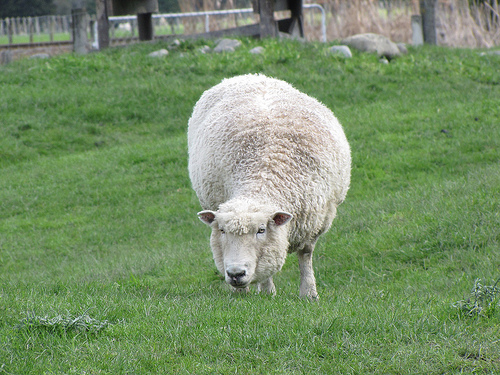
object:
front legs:
[298, 235, 321, 300]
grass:
[348, 293, 414, 335]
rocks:
[327, 30, 410, 63]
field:
[20, 63, 138, 318]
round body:
[184, 72, 354, 251]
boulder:
[336, 32, 401, 59]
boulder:
[323, 44, 353, 60]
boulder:
[210, 37, 246, 56]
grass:
[0, 71, 121, 116]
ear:
[269, 210, 295, 226]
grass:
[355, 147, 461, 171]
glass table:
[366, 205, 466, 345]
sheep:
[187, 70, 352, 299]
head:
[196, 198, 294, 289]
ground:
[431, 89, 449, 120]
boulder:
[247, 45, 265, 54]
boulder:
[325, 43, 353, 56]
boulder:
[340, 31, 402, 56]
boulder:
[213, 37, 240, 53]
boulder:
[194, 43, 211, 55]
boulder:
[146, 47, 171, 57]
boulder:
[170, 35, 180, 47]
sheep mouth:
[225, 275, 253, 289]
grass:
[374, 50, 491, 372]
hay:
[301, 0, 499, 46]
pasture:
[1, 1, 499, 371]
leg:
[256, 278, 278, 295]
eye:
[255, 227, 266, 237]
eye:
[216, 226, 229, 235]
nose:
[226, 267, 247, 277]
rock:
[343, 27, 403, 61]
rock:
[318, 41, 356, 62]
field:
[0, 40, 493, 372]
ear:
[197, 209, 219, 226]